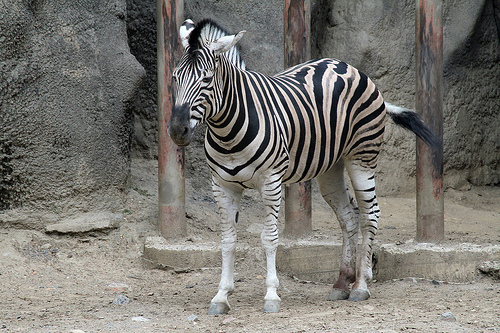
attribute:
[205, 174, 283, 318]
front legs — of the zebra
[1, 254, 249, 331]
ground — beneath the zebra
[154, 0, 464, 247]
wooden poles — three, behind the zebra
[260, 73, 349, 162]
stripes — black and white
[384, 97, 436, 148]
zebra tail — black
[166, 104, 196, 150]
black nose — of zebra